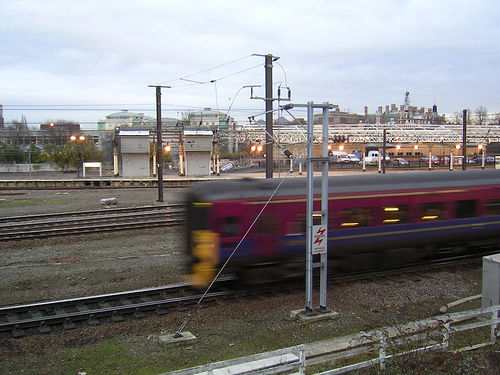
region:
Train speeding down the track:
[137, 155, 494, 277]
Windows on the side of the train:
[335, 210, 492, 225]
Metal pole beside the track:
[273, 98, 349, 327]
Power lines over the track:
[111, 56, 427, 136]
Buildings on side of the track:
[48, 81, 321, 178]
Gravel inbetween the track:
[72, 240, 144, 282]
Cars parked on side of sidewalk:
[327, 126, 417, 166]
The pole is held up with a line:
[132, 303, 235, 338]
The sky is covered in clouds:
[19, 32, 147, 122]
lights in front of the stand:
[359, 96, 494, 161]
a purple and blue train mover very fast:
[195, 175, 491, 290]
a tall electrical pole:
[146, 70, 180, 217]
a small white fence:
[284, 310, 473, 367]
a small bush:
[403, 345, 495, 373]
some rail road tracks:
[25, 283, 167, 332]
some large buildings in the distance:
[342, 88, 436, 125]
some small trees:
[33, 137, 105, 168]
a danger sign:
[300, 208, 332, 264]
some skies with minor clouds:
[57, 15, 197, 63]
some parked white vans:
[330, 145, 362, 168]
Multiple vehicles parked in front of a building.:
[315, 147, 498, 172]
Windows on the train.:
[268, 195, 498, 234]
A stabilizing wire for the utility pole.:
[157, 135, 311, 336]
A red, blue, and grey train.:
[179, 162, 498, 284]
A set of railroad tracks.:
[4, 193, 185, 255]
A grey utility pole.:
[282, 97, 342, 327]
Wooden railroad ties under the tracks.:
[63, 293, 101, 328]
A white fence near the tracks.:
[158, 290, 498, 373]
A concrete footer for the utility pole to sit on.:
[285, 303, 340, 323]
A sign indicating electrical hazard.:
[310, 224, 331, 256]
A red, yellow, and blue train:
[179, 160, 498, 275]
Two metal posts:
[299, 93, 335, 318]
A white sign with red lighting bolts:
[307, 221, 330, 259]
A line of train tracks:
[0, 280, 195, 326]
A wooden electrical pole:
[146, 78, 171, 208]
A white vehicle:
[360, 148, 385, 166]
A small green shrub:
[346, 285, 450, 371]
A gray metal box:
[475, 250, 498, 305]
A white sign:
[78, 159, 105, 181]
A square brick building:
[37, 118, 84, 140]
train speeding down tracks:
[169, 171, 496, 264]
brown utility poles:
[140, 60, 299, 196]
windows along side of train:
[215, 185, 491, 242]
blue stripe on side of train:
[215, 219, 497, 257]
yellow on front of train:
[185, 202, 225, 289]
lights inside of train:
[282, 201, 462, 226]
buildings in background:
[6, 102, 141, 165]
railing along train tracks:
[236, 317, 495, 374]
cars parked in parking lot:
[321, 135, 448, 173]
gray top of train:
[192, 163, 497, 201]